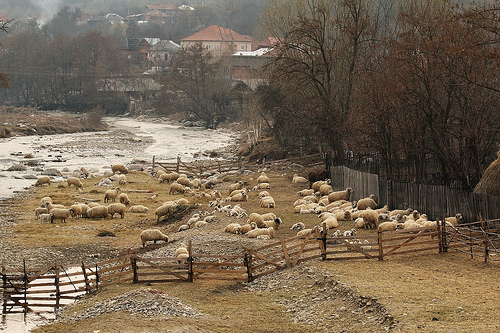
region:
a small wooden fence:
[1, 241, 494, 328]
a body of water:
[41, 88, 271, 181]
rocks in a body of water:
[18, 80, 248, 173]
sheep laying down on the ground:
[186, 126, 422, 268]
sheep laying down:
[222, 158, 446, 273]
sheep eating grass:
[53, 173, 155, 250]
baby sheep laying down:
[170, 199, 293, 251]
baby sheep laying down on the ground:
[164, 186, 269, 251]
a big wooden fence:
[328, 163, 497, 228]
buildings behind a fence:
[88, 8, 345, 92]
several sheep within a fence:
[11, 154, 473, 309]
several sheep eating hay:
[35, 193, 132, 227]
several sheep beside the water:
[21, 148, 91, 189]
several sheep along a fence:
[298, 168, 418, 220]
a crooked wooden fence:
[9, 251, 283, 296]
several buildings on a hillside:
[139, 18, 271, 80]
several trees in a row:
[262, 5, 497, 141]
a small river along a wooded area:
[1, 50, 245, 167]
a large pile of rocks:
[75, 283, 181, 325]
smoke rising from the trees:
[28, 0, 68, 39]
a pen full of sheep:
[33, 159, 465, 256]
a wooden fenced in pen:
[9, 220, 465, 311]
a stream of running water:
[32, 114, 208, 176]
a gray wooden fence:
[388, 183, 485, 226]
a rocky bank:
[299, 275, 382, 330]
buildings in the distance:
[101, 66, 275, 116]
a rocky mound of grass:
[127, 287, 194, 322]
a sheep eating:
[138, 228, 170, 248]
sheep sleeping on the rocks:
[192, 205, 237, 237]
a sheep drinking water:
[29, 172, 51, 192]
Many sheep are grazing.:
[22, 159, 444, 247]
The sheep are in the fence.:
[32, 165, 451, 242]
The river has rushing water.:
[7, 112, 236, 186]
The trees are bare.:
[236, 2, 494, 195]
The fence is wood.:
[5, 222, 497, 312]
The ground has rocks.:
[133, 237, 353, 331]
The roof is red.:
[180, 10, 246, 47]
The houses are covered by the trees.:
[81, 21, 296, 102]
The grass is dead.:
[37, 159, 468, 331]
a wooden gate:
[129, 250, 193, 290]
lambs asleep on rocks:
[182, 211, 214, 231]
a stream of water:
[21, 110, 204, 206]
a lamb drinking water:
[30, 172, 55, 187]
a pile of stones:
[90, 280, 190, 320]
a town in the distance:
[51, 10, 286, 100]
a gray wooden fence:
[315, 172, 460, 217]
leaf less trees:
[266, 0, 497, 150]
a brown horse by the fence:
[305, 168, 330, 185]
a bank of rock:
[258, 278, 393, 318]